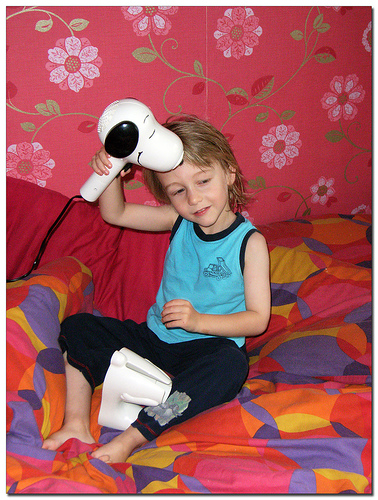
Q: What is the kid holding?
A: Hair dryer.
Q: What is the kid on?
A: A bed.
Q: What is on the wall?
A: Flowers.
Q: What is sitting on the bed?
A: The young girl.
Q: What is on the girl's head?
A: Blonde wet hair.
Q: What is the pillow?
A: Red.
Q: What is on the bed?
A: Colorful comforter.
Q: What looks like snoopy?
A: The blow dryer.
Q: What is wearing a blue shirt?
A: The girl.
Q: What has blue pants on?
A: The girl.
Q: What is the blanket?
A: Colorful.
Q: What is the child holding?
A: A hair dryer.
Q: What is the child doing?
A: Drying hair.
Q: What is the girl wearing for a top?
A: A light blue tank top.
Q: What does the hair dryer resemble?
A: A dog.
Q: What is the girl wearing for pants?
A: Sweatpants.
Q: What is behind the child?
A: A pink background.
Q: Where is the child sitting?
A: On the bed.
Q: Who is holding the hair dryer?
A: The child.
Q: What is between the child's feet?
A: The hair dryer cover.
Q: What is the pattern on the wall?
A: A floral pattern.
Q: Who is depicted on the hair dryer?
A: Snoopy.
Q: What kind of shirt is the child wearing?
A: A tank top.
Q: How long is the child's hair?
A: To the child's shoulders.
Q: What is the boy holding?
A: Hair dryer.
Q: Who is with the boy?
A: No one.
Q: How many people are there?
A: One.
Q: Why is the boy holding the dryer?
A: Drying hair.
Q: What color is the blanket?
A: Multi-color.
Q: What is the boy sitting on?
A: Bed.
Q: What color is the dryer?
A: White.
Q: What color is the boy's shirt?
A: Blue.